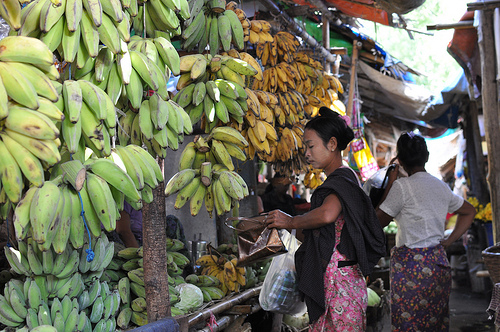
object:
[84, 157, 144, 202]
bananas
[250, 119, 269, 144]
bananas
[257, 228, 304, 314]
bag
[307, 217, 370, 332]
garmet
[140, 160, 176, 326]
trunk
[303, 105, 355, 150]
hair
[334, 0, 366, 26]
canvas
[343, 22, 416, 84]
tarp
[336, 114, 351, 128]
clip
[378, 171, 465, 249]
shirt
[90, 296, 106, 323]
bananas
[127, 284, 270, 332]
table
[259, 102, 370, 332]
women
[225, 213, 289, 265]
bag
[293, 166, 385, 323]
blanket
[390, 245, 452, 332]
skirt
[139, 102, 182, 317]
banana tree